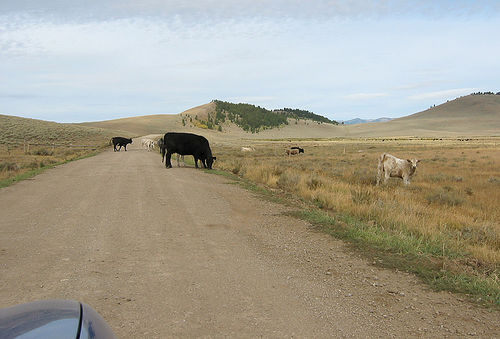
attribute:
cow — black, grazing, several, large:
[163, 132, 216, 169]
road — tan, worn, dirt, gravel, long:
[0, 133, 499, 338]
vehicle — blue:
[0, 299, 121, 338]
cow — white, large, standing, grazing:
[241, 147, 257, 152]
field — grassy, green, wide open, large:
[152, 135, 499, 309]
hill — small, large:
[181, 99, 290, 133]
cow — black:
[111, 137, 133, 152]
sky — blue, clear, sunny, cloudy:
[0, 1, 500, 123]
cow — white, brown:
[378, 153, 422, 185]